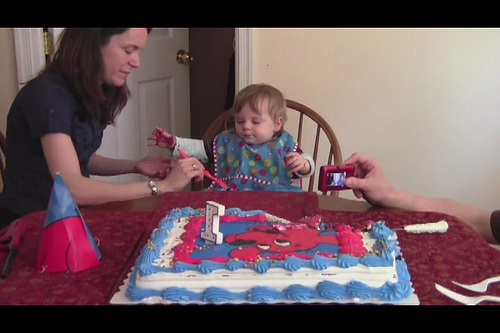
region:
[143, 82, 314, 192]
toddler at birthday party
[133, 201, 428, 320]
birthday cake with Big Red Dog decoration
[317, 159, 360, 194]
camera taking photo of child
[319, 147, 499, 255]
person holding camera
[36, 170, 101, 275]
paper birthday hat in shape of cone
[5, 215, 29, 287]
lighter for lighting candle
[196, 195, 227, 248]
candle in shape of number one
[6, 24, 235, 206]
woman feeding child cake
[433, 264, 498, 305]
plastic forks for eating cake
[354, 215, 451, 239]
cake knife next to cut cake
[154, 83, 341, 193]
Baby sitting in highchair at table.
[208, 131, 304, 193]
Bib around baby's neck.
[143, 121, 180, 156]
Pink cake icing on baby's hand.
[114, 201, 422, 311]
Birthday cake on table in front of baby.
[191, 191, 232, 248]
White candle on cake indicates baby's age.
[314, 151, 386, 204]
Hand of man taking picture of baby.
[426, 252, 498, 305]
Two white plastic forks laying on table next to cake.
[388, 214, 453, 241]
Handle of spatula used to lift cut cake.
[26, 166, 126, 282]
Pink and blue birthday hat on table.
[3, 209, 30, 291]
Lighter used to light birthday candle.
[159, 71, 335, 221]
A birthday party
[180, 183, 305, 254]
A one year birthday party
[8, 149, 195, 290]
A birthday hat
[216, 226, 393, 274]
A cake with a dog on it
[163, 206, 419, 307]
A Clifford the dog cake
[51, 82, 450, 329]
People at the birthday party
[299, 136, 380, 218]
A camera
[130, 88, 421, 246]
A baby eating cake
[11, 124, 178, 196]
Mom helping baby eat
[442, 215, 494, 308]
Plastic forks on the table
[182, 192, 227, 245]
a number candle on a cake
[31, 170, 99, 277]
a party hat on the table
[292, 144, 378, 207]
a hand holding a camera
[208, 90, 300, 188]
a baby wearing a bib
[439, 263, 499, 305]
white plastic forks lying on the table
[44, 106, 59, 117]
a button on the sleeve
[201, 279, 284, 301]
blue frosting around the cake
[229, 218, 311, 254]
a picture of a red dog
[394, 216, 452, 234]
the handle of a cake cutter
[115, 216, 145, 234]
a floral table cloth on the table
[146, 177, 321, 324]
Birthday party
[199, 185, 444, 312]
Clifford the dog cake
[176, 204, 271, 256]
A number one birthday candle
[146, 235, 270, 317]
Icing on the cake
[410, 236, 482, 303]
Plastic forks on the table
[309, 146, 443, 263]
Using the camera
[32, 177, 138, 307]
birthday hat on the table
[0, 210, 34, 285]
A lighter sitting on the table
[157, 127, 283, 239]
A mother helping the child eat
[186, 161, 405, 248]
Cake was cut